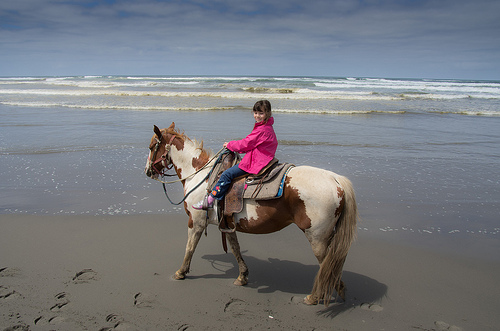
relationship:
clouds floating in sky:
[33, 15, 469, 70] [3, 1, 498, 78]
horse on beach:
[145, 122, 355, 303] [2, 212, 482, 323]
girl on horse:
[201, 100, 277, 209] [145, 122, 355, 303]